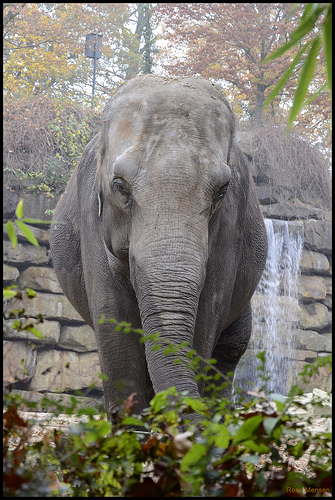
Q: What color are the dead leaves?
A: Orange.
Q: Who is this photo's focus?
A: The elephant.